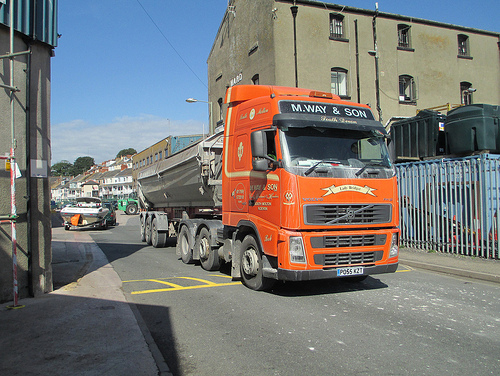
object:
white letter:
[291, 104, 368, 119]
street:
[95, 237, 499, 369]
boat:
[59, 196, 116, 229]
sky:
[59, 18, 151, 82]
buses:
[390, 104, 500, 245]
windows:
[329, 66, 348, 99]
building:
[206, 0, 498, 135]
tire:
[239, 234, 275, 290]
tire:
[198, 227, 222, 271]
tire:
[179, 224, 200, 263]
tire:
[151, 217, 167, 247]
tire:
[126, 204, 138, 215]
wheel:
[126, 205, 137, 215]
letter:
[315, 105, 323, 114]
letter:
[344, 108, 352, 117]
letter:
[352, 109, 359, 117]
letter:
[358, 110, 367, 119]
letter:
[304, 104, 315, 112]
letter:
[344, 106, 351, 115]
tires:
[140, 217, 146, 242]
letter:
[291, 104, 303, 112]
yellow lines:
[130, 284, 209, 294]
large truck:
[132, 84, 401, 291]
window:
[327, 10, 349, 43]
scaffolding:
[0, 0, 32, 305]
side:
[0, 0, 54, 304]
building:
[0, 0, 59, 306]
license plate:
[337, 266, 364, 276]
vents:
[324, 205, 377, 270]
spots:
[427, 294, 433, 297]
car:
[60, 197, 117, 230]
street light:
[186, 98, 214, 134]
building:
[99, 168, 136, 199]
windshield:
[285, 128, 396, 177]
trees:
[74, 156, 94, 172]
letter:
[319, 105, 327, 113]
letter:
[332, 107, 340, 115]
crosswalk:
[119, 262, 415, 296]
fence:
[395, 154, 500, 261]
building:
[131, 135, 208, 196]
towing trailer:
[117, 198, 148, 215]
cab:
[220, 84, 400, 292]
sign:
[291, 104, 368, 119]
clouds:
[54, 123, 135, 160]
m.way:
[291, 104, 327, 114]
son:
[344, 108, 368, 119]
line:
[209, 274, 232, 278]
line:
[158, 272, 217, 285]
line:
[131, 281, 242, 294]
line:
[122, 279, 183, 288]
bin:
[444, 104, 500, 155]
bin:
[390, 109, 448, 162]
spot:
[309, 347, 316, 350]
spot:
[338, 340, 346, 344]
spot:
[377, 303, 385, 311]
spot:
[446, 327, 454, 331]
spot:
[393, 295, 399, 297]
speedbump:
[119, 264, 412, 295]